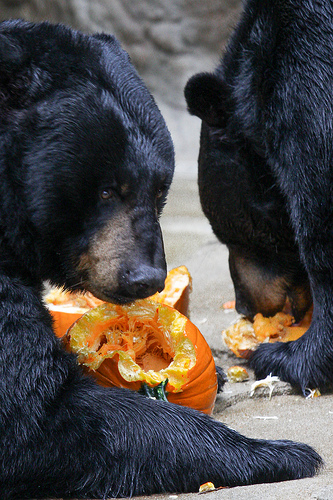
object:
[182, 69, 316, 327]
heads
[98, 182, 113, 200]
eye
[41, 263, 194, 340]
pumpkin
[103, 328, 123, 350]
stuff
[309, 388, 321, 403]
pumpkin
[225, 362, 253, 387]
pumpkin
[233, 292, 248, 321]
nose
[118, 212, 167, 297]
snout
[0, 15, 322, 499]
bear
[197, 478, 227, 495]
pumpkin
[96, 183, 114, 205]
eyes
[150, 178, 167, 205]
eyes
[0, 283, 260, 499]
arm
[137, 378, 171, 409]
stem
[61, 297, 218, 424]
pumpkin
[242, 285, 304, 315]
mouth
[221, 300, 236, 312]
pumpkin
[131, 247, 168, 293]
nose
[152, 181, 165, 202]
eye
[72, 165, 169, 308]
face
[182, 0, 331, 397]
bear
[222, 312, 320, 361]
pumpkin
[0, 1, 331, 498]
zoo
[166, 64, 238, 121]
ear